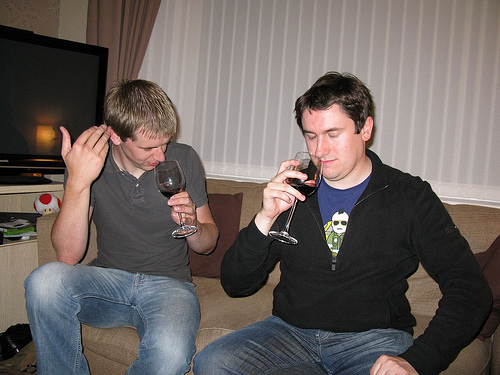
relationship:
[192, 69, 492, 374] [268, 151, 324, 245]
man holding wine glass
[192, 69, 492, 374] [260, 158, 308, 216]
man has hand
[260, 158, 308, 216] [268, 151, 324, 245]
hand holding wine glass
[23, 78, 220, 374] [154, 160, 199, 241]
man holding wine glass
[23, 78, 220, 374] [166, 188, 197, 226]
man has hand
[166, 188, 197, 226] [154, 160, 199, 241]
hand holding wine glass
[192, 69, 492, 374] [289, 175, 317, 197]
man smelling wine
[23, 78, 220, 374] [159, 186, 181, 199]
man smelling wine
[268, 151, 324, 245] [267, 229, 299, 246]
wine glass has base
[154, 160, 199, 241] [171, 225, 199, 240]
wine glass has base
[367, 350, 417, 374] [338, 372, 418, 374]
hand on top of knee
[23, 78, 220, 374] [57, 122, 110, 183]
man has hand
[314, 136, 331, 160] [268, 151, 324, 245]
nose inside wine glass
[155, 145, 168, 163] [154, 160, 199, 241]
nose inside wine glass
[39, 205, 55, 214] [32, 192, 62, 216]
head of mushroom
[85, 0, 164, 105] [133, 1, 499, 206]
curtain draped next to window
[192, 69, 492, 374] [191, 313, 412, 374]
man wearing jeans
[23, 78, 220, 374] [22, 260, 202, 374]
man wearing jeans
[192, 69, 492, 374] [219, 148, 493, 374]
man wearing fleece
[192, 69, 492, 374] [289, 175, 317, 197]
man drinking wine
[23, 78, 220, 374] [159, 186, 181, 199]
man drinking wine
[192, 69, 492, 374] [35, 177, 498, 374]
man sitting on couch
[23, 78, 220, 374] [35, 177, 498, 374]
man sitting on couch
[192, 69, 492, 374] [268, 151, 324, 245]
man tilting wine glass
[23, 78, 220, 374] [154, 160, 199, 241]
man tilting wine glass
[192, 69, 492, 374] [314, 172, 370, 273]
man wearing shirt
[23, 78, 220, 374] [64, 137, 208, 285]
man wearing shirt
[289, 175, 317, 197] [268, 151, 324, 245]
wine inside of wine glass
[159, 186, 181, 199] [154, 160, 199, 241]
wine inside of wine glass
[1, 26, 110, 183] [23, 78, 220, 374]
television next to man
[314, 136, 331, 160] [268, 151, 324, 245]
nose inside of wine glass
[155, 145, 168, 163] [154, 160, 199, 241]
nose inside of wine glass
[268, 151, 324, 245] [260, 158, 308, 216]
wine glass held in hand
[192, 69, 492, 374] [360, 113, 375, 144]
man has left ear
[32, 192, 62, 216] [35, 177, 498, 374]
mushroom next to couch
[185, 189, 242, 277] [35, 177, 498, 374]
pillow on top of couch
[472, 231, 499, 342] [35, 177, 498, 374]
pillow on top of couch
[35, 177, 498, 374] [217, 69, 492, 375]
couch beneath man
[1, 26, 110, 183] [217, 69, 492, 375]
television near man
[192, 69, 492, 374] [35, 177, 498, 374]
man sitting on top of couch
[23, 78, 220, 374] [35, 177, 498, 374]
man sitting on top of couch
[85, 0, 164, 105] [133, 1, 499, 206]
curtain next to window